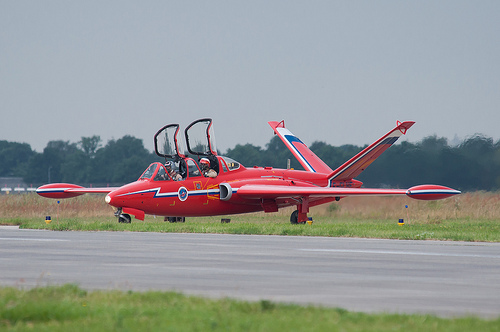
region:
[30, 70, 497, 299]
a small, red airplane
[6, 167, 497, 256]
a large, beautiful grassy field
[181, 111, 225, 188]
an open airplane cockpit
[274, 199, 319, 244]
wheels of a small plane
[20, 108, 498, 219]
a dark line of trees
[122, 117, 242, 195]
two pilots in the cockpit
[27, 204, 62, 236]
small airstrip lighting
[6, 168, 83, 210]
nondescript buildings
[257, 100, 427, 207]
V-shaped plane tail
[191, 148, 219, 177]
a pilot wearing a red helmet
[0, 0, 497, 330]
an outdoor scene of a jet at an airstrip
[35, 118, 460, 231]
a red 2man jet taxing on a tarmac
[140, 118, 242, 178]
the jets open cockpit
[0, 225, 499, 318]
a paved landing strip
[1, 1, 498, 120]
the sky is grey and hazy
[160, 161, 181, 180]
the jets pilot in the front of the cockpit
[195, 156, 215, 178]
the copilot in the back of the cockpit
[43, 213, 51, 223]
the tarmac marker cones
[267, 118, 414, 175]
the red, blue and white tail of the jet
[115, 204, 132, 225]
the front landing gear of the jet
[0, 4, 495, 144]
sky is overcast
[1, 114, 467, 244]
red, white, and blue plane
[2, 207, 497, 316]
concrete pavement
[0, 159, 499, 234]
green and brown grass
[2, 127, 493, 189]
dark green trees in the background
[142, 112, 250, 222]
two people flying the plane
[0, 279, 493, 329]
green grass strip in the foreground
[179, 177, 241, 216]
specks of yellow on the side of the plane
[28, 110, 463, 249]
plane is on the grass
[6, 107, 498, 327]
the field is empty except for the plane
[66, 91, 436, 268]
red plane on ground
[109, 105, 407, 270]
red, blue and white plane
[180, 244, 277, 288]
gray cement next to plane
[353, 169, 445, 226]
wing of the plane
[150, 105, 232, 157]
windshield of plane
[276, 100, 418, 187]
tail of the back of plane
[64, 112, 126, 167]
trees in background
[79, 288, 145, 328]
green grass next to cement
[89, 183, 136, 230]
nose of the plane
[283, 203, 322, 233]
wheel of the plane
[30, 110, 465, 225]
Red, white and purple airplane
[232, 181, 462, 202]
Left wing of airplane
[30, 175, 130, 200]
Right wing of airplane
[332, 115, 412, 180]
Left tail wing of airplane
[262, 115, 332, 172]
Right tail wing of airplane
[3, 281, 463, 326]
Grass on side of landing strip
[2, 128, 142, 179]
Tall trees in the background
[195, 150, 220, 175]
Pilot sitting in the back seat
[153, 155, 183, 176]
Pilot sitting in the front seat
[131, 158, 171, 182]
Front windshield of plane